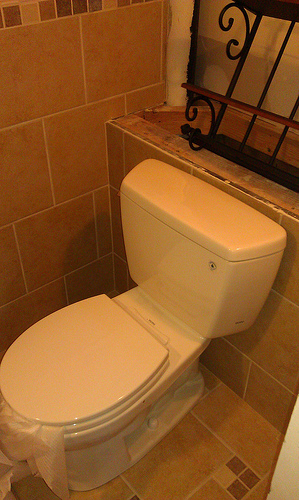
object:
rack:
[179, 0, 298, 188]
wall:
[162, 4, 298, 135]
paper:
[0, 398, 68, 500]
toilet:
[0, 160, 286, 492]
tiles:
[212, 450, 255, 500]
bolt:
[148, 417, 158, 430]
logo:
[209, 261, 216, 270]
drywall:
[98, 98, 299, 440]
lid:
[0, 293, 169, 425]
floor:
[0, 337, 299, 498]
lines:
[221, 339, 299, 407]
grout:
[228, 338, 296, 406]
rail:
[182, 0, 299, 192]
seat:
[0, 293, 167, 436]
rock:
[102, 115, 298, 217]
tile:
[0, 0, 154, 31]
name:
[210, 261, 217, 271]